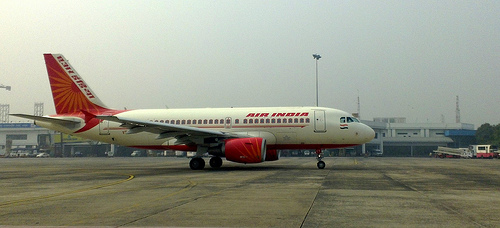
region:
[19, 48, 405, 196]
the plane is white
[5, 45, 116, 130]
the tail of the plane is red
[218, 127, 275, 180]
the engine is red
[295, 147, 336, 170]
the wheel is black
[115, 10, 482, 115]
the sky is overcast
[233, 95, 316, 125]
the letters are red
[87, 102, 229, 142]
short building in the background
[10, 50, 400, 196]
the plane is still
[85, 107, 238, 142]
the wing is grey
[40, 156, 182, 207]
lines on the ground are yellow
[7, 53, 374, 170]
red and white airplane is parked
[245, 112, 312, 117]
red writing on airplane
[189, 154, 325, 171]
black wheels under airplane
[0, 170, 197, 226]
yellow lines behind airplane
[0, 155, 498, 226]
cement lot under airplane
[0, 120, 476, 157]
airport behind airplane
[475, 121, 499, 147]
trees next to airport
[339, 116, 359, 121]
windshield windows on airplane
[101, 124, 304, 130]
long red line on airplane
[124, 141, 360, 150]
underside of airplane is red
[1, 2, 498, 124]
cloud cover in sky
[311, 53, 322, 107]
light on tall pole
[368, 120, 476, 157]
side of airport terminal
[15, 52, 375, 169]
side of parked airplane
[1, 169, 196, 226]
yellow lines on tarmac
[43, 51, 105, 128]
disign on plane tail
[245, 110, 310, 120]
two red words on plane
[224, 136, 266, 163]
side of red jet engine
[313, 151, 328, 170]
wheel of landing gear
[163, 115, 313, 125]
windows on side of plane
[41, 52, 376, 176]
A plane on the runway.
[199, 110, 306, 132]
The plane has windows.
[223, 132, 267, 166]
A red engine on the plane.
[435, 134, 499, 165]
Vehicles parked at the terminal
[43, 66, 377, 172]
The plane is red and white.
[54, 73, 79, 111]
A yellow sun on the tail of plane.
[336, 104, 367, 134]
The cockpit of the plane.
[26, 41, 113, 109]
The red tail of the plane.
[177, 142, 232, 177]
Tires on the plane.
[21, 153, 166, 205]
Yellow line on the pavement.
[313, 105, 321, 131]
part of a door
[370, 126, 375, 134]
tip of a plane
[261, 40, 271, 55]
part of the cloud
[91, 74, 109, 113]
back of a plane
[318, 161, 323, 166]
part of a wheel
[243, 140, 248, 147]
part of a wing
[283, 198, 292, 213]
part of a run way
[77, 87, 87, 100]
back of a plane